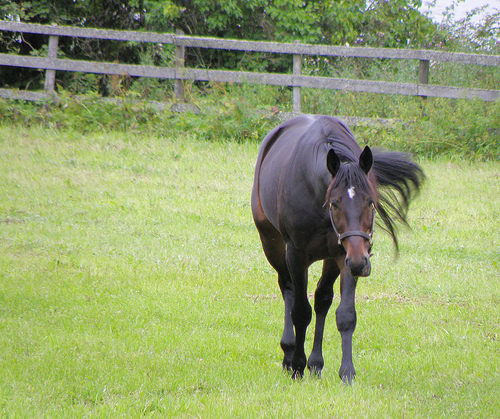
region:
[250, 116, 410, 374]
the horse is walking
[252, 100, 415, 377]
the horse is brown and black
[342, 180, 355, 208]
the horse has a white dot on its face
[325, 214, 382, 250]
the horse has a harness on his face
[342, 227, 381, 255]
the harness is made of leather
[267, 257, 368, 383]
the horse has four legs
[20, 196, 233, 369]
the grass in the field is green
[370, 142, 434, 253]
the horse's tail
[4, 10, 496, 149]
a wooden fence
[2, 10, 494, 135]
the wooden fence is gray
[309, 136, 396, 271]
the head of a brown horse.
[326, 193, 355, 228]
the right eye of a horse.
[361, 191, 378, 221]
the left eye of a horse.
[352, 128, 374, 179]
the left ear of a horse.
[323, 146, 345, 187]
the right ear of a horse.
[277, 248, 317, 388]
the right leg of a horse.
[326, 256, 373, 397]
the left leg of a horse.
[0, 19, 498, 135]
a wooden fence in a field.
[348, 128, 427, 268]
the black tail of a horse.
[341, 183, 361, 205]
a white spot on a horses forehead.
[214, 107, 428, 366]
the horse is black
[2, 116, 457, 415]
the horse is walking in a grassy field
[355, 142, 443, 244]
the horse has a black tail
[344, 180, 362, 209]
the horse has a white dot on his head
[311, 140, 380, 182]
the horse's ears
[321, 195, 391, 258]
the horse is wearing a harness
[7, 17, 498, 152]
the fence is gray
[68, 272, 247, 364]
the grass is tall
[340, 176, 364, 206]
a white forehead spot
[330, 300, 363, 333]
the front left knee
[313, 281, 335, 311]
the back left knee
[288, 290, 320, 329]
the front right knee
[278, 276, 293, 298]
the back right knee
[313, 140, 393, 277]
a black horse head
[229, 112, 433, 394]
this is a horse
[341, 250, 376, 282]
a brown horse nose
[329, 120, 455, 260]
a black horses mane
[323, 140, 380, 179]
some brown horse ears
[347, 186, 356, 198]
white spot on horses head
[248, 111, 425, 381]
horse is brown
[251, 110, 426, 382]
horse walking in a grassy field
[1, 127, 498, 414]
field is green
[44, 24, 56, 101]
wooden gray fence post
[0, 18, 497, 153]
wooden fence behind horse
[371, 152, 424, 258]
black tail of horse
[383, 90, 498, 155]
bush next to fence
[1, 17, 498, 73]
top rail of wooden gray fence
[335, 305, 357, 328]
knee of horse